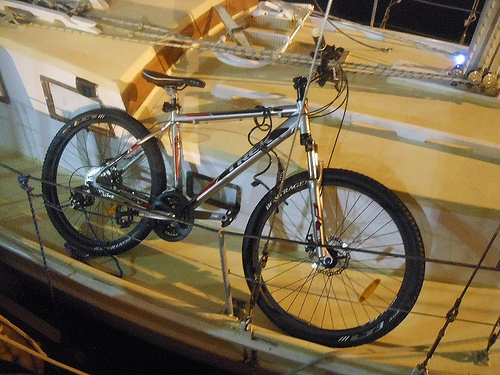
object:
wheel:
[240, 165, 425, 349]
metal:
[85, 168, 114, 195]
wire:
[249, 102, 285, 196]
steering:
[295, 28, 349, 86]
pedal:
[218, 203, 242, 231]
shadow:
[2, 148, 268, 320]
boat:
[1, 2, 499, 374]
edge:
[0, 231, 416, 373]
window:
[184, 172, 241, 209]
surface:
[0, 0, 498, 372]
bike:
[38, 26, 427, 350]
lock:
[250, 103, 285, 201]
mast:
[456, 2, 499, 94]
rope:
[0, 3, 497, 89]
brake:
[302, 61, 351, 258]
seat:
[140, 67, 207, 90]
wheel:
[42, 107, 166, 254]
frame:
[92, 78, 331, 268]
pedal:
[115, 200, 136, 230]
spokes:
[255, 185, 406, 331]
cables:
[0, 164, 498, 375]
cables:
[299, 63, 351, 244]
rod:
[190, 113, 301, 210]